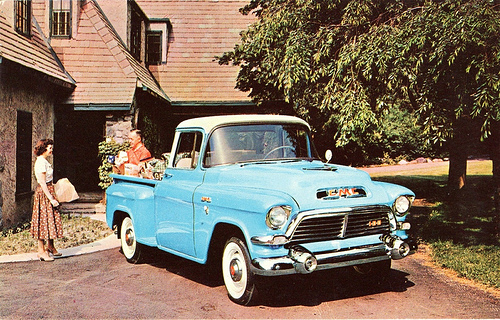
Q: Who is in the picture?
A: A man and woman.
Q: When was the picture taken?
A: Daytime.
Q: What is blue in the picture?
A: The car.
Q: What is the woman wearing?
A: Shirt, skirt and shoes.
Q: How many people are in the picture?
A: Two.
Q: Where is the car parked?
A: A driveway.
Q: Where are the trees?
A: On the right.